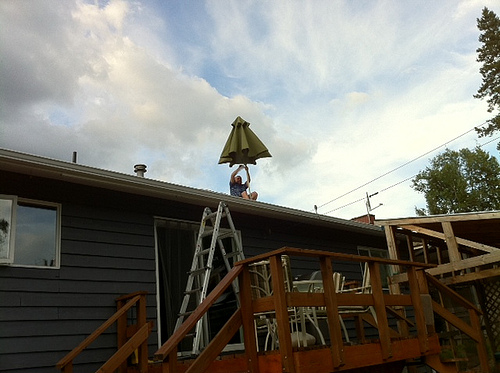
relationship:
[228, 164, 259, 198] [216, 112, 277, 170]
person holding umbrella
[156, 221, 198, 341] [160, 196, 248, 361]
door behind ladder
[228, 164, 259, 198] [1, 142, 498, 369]
person on top of building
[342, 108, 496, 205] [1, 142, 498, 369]
power lines near building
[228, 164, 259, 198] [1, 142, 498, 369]
person sitting on building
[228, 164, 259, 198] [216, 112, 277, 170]
person holds umbrella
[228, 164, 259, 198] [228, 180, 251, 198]
person wearing shirt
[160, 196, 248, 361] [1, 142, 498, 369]
ladder near building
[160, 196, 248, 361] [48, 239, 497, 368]
ladder near deck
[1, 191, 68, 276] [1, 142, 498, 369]
window of a building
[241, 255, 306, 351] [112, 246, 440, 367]
outdoor furniture sitting on patio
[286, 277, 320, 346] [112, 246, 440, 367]
outdoor furniture sitting on patio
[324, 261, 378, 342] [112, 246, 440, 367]
outdoor furniture sitting on patio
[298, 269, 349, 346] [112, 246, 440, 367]
outdoor furniture sitting on patio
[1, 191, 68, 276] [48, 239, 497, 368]
window beside deck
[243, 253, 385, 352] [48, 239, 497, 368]
furniture on deck